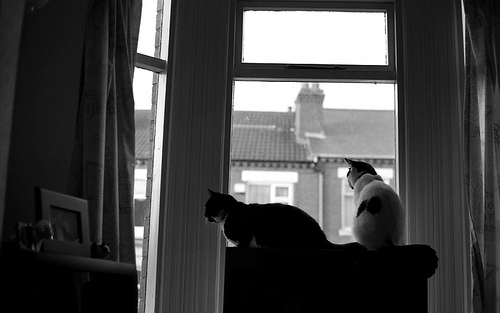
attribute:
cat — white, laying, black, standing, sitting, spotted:
[334, 152, 406, 260]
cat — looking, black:
[195, 183, 364, 260]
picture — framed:
[27, 182, 92, 253]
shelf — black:
[31, 250, 137, 291]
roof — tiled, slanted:
[236, 106, 396, 164]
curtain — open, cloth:
[3, 8, 138, 262]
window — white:
[123, 14, 179, 272]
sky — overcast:
[241, 13, 394, 112]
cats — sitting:
[195, 148, 441, 279]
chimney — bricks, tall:
[290, 83, 325, 142]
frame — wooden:
[32, 187, 109, 260]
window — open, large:
[239, 7, 401, 256]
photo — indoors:
[5, 4, 499, 311]